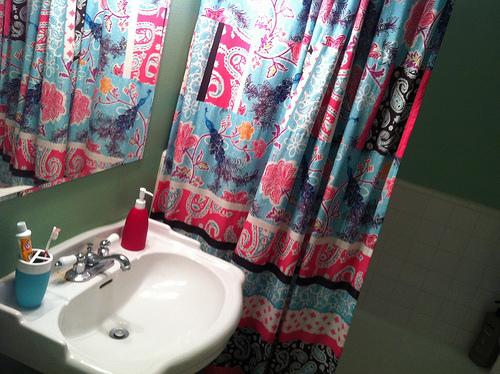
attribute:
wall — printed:
[355, 174, 461, 196]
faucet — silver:
[64, 232, 132, 283]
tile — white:
[412, 215, 444, 248]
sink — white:
[1, 215, 248, 372]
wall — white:
[415, 128, 493, 235]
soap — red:
[120, 182, 152, 254]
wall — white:
[391, 217, 492, 318]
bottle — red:
[119, 181, 159, 256]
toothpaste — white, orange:
[14, 221, 31, 261]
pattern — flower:
[150, 26, 395, 283]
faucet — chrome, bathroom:
[48, 232, 134, 277]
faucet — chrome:
[55, 232, 130, 281]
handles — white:
[56, 233, 117, 270]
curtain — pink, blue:
[175, 12, 443, 267]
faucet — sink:
[72, 237, 137, 276]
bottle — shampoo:
[467, 299, 499, 372]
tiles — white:
[357, 177, 499, 361]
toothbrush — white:
[23, 218, 68, 263]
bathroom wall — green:
[364, 3, 499, 342]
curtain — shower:
[134, 5, 462, 353]